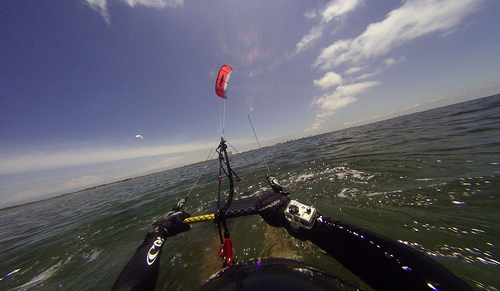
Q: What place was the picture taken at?
A: It was taken at the ocean.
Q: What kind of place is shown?
A: It is an ocean.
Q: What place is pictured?
A: It is an ocean.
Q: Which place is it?
A: It is an ocean.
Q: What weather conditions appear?
A: It is clear.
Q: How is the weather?
A: It is clear.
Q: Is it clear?
A: Yes, it is clear.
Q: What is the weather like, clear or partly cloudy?
A: It is clear.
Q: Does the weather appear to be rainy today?
A: No, it is clear.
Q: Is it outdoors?
A: Yes, it is outdoors.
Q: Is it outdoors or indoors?
A: It is outdoors.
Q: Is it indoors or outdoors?
A: It is outdoors.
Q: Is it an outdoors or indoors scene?
A: It is outdoors.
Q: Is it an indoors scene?
A: No, it is outdoors.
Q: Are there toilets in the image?
A: No, there are no toilets.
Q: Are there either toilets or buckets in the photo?
A: No, there are no toilets or buckets.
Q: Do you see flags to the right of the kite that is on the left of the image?
A: No, there is a parachute to the right of the kite.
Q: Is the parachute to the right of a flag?
A: No, the parachute is to the right of the kite.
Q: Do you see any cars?
A: No, there are no cars.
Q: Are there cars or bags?
A: No, there are no cars or bags.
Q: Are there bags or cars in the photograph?
A: No, there are no cars or bags.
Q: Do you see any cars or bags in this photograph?
A: No, there are no cars or bags.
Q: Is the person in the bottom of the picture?
A: Yes, the person is in the bottom of the image.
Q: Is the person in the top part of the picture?
A: No, the person is in the bottom of the image.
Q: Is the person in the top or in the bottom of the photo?
A: The person is in the bottom of the image.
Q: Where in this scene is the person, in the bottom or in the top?
A: The person is in the bottom of the image.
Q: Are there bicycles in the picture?
A: No, there are no bicycles.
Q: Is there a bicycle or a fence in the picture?
A: No, there are no bicycles or fences.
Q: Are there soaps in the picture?
A: No, there are no soaps.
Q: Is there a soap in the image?
A: No, there are no soaps.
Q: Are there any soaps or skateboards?
A: No, there are no soaps or skateboards.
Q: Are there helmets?
A: No, there are no helmets.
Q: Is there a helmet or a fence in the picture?
A: No, there are no helmets or fences.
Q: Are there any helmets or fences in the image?
A: No, there are no helmets or fences.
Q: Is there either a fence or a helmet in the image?
A: No, there are no helmets or fences.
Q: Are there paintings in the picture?
A: No, there are no paintings.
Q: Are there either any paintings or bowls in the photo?
A: No, there are no paintings or bowls.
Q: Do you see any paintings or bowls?
A: No, there are no paintings or bowls.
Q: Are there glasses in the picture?
A: No, there are no glasses.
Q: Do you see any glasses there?
A: No, there are no glasses.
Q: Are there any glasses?
A: No, there are no glasses.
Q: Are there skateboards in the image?
A: No, there are no skateboards.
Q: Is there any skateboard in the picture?
A: No, there are no skateboards.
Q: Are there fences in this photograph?
A: No, there are no fences.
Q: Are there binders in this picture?
A: No, there are no binders.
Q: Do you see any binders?
A: No, there are no binders.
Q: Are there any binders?
A: No, there are no binders.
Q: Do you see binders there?
A: No, there are no binders.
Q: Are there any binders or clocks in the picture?
A: No, there are no binders or clocks.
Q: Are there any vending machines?
A: No, there are no vending machines.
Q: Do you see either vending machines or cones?
A: No, there are no vending machines or cones.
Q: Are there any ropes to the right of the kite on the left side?
A: Yes, there are ropes to the right of the kite.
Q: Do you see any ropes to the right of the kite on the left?
A: Yes, there are ropes to the right of the kite.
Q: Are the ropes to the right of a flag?
A: No, the ropes are to the right of the kite.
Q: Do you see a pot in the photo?
A: No, there are no pots.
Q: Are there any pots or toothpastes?
A: No, there are no pots or toothpastes.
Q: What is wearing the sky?
A: The clouds are wearing the sky.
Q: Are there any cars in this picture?
A: No, there are no cars.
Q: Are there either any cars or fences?
A: No, there are no cars or fences.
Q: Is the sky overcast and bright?
A: No, the sky is bright but clear.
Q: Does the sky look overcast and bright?
A: No, the sky is bright but clear.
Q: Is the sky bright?
A: Yes, the sky is bright.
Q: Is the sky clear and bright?
A: Yes, the sky is clear and bright.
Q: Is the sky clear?
A: Yes, the sky is clear.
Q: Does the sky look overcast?
A: No, the sky is clear.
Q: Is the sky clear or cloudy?
A: The sky is clear.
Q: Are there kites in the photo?
A: Yes, there is a kite.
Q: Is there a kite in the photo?
A: Yes, there is a kite.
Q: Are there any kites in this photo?
A: Yes, there is a kite.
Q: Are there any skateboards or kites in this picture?
A: Yes, there is a kite.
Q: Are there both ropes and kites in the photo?
A: Yes, there are both a kite and a rope.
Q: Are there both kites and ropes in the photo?
A: Yes, there are both a kite and a rope.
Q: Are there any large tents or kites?
A: Yes, there is a large kite.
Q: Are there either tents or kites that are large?
A: Yes, the kite is large.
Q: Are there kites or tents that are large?
A: Yes, the kite is large.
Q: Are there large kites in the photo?
A: Yes, there is a large kite.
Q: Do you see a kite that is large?
A: Yes, there is a kite that is large.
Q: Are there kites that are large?
A: Yes, there is a kite that is large.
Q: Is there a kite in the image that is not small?
A: Yes, there is a large kite.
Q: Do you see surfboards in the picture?
A: No, there are no surfboards.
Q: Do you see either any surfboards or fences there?
A: No, there are no surfboards or fences.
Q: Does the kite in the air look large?
A: Yes, the kite is large.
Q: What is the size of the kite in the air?
A: The kite is large.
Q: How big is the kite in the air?
A: The kite is large.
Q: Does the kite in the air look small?
A: No, the kite is large.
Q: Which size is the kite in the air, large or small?
A: The kite is large.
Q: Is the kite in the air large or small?
A: The kite is large.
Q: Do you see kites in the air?
A: Yes, there is a kite in the air.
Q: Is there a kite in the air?
A: Yes, there is a kite in the air.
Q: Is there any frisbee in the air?
A: No, there is a kite in the air.